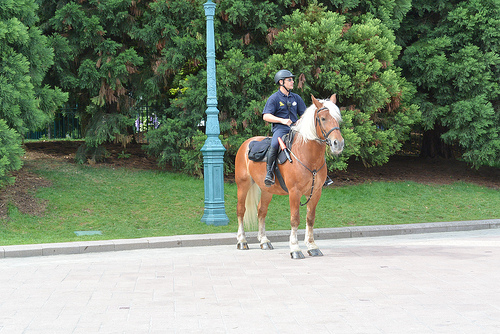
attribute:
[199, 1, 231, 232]
pole — gray, tall, long, green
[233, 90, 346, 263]
horse — brown, mounted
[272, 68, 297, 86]
helmet — black, dark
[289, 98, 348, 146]
mane — white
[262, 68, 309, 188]
officer — police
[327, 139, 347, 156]
nose — grey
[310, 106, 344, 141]
harness — black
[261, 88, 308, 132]
shirt — blue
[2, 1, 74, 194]
pinetree — healthy, green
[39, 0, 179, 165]
tree — beautiful, green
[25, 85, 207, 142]
fence — black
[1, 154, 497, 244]
grass — green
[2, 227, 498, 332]
street — gray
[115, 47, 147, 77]
leaves — green